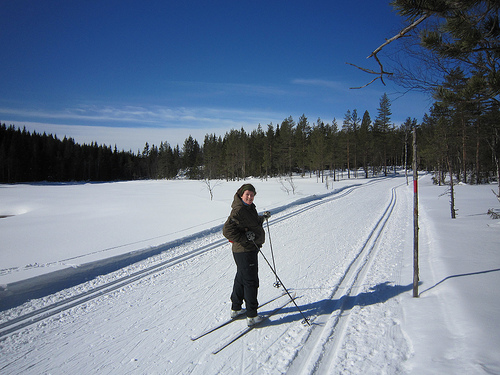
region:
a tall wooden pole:
[390, 110, 435, 300]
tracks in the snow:
[22, 224, 160, 336]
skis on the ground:
[178, 274, 311, 370]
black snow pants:
[206, 225, 295, 320]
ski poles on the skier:
[243, 230, 342, 342]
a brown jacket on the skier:
[215, 178, 282, 253]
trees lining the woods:
[197, 115, 336, 171]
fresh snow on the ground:
[102, 196, 159, 242]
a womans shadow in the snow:
[267, 257, 438, 332]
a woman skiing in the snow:
[156, 161, 344, 373]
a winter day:
[11, 58, 488, 370]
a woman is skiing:
[186, 178, 323, 356]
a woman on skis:
[190, 172, 316, 357]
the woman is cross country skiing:
[186, 176, 329, 358]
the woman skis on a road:
[182, 177, 322, 362]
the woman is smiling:
[181, 178, 332, 360]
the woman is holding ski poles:
[183, 176, 325, 363]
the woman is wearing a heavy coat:
[172, 178, 322, 362]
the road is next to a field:
[6, 165, 414, 373]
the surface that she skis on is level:
[173, 175, 336, 362]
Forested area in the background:
[0, 114, 493, 175]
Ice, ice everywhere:
[3, 191, 197, 368]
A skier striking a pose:
[223, 182, 271, 328]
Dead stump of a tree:
[406, 120, 424, 300]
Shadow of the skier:
[267, 276, 422, 330]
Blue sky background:
[1, 2, 342, 107]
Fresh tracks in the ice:
[322, 183, 402, 295]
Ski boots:
[228, 301, 269, 328]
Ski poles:
[258, 209, 318, 321]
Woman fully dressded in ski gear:
[196, 183, 321, 346]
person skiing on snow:
[153, 156, 305, 357]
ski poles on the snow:
[211, 247, 313, 332]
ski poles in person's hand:
[231, 214, 351, 308]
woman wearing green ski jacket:
[196, 187, 274, 276]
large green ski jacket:
[162, 193, 261, 265]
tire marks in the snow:
[76, 170, 204, 302]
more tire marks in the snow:
[279, 193, 428, 313]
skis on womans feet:
[177, 288, 305, 373]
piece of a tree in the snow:
[346, 96, 425, 283]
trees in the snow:
[93, 105, 370, 321]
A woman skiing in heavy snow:
[192, 176, 317, 352]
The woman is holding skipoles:
[250, 217, 312, 320]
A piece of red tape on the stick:
[410, 175, 418, 195]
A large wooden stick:
[399, 120, 427, 297]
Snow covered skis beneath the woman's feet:
[202, 294, 290, 341]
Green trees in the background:
[2, 144, 130, 179]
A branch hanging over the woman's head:
[351, 10, 432, 85]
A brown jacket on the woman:
[226, 198, 261, 249]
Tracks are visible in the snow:
[353, 175, 413, 370]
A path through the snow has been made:
[201, 179, 402, 360]